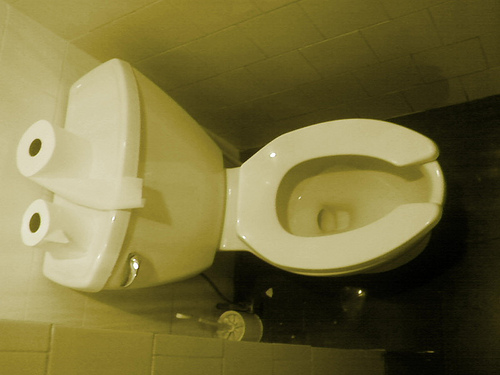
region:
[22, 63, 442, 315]
toilet on the floor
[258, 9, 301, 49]
tile on the wall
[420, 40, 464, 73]
tile on the wall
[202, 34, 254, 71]
tile on the wall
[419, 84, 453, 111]
tile on the wall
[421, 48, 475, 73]
tile on the wall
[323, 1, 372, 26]
tile on the wall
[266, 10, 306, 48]
tile on the wall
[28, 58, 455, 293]
white porcelain toilet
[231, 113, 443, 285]
toilet seat is down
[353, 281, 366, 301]
light glare on the floor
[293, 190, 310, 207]
light glare on the bowl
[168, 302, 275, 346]
toilet brush in its holder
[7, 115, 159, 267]
two rolls of toilet paper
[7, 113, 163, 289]
toilet paper on top of the toilet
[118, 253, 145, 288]
silver handle on the toilet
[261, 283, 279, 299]
small piece of toilet paper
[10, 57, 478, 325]
this is a toilet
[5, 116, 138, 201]
a large roll of toilet paper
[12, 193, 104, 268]
a small roll of toilet paper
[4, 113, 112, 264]
two rolls of toilet paper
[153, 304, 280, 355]
this is a toilet brush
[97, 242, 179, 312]
the knob to flush a toilet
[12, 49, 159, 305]
the toilet tank lid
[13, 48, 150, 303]
the toilet paper is on the tank lid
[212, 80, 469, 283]
the toilet seat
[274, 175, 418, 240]
water in the toilet bowl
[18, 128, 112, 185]
full toilet paper roll on top of the bowl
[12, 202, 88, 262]
half full toilet paper roll on top of the bowl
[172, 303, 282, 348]
toilet brush in a container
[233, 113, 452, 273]
white toilet seat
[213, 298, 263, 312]
water line to the toilet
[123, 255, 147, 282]
handle on the toilet bowl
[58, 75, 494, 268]
white toilet in the bathroom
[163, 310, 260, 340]
the white toilet brush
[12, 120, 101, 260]
two rolls of toilet paper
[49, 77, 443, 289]
a white toilet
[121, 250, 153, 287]
the silver toilet handle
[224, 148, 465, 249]
the seat of the toilet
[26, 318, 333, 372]
the brick wall of the stall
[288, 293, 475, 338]
the floor of the bathroom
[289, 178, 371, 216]
water in the toilet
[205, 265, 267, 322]
a pipe going to the toilet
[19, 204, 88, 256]
a smaller roll of toilet paper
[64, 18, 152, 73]
a tile in a wall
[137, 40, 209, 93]
a tile in a wall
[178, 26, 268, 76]
a tile in a wall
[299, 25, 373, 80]
a tile in a wall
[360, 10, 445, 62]
a tile in a wall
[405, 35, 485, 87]
a tile in a wall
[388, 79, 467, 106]
a tile in a wall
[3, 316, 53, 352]
a brick in a wall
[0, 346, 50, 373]
a brick in a wall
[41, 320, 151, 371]
a brick in a wall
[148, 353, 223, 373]
a brick in a wall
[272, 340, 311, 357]
a brick in a wall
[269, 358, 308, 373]
a brick in a wall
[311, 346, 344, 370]
a brick in a wall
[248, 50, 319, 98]
a brick in a wall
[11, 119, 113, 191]
toilet roll on the toilet